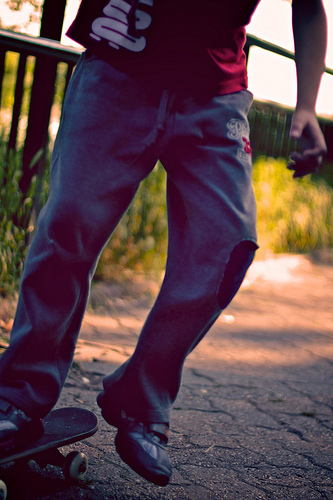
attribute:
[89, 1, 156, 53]
text — white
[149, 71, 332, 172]
fence — black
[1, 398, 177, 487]
tennis shoes — dark blue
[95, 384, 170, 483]
shoe — black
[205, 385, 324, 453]
pavement — cracked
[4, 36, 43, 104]
fence — shining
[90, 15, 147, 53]
letter — white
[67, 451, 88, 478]
wheel — white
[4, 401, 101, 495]
skateboard — dark 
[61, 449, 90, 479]
wheels — white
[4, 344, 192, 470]
tennis shoes — black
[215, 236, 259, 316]
pad — blue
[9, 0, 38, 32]
leaves — green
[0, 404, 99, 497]
skateboard — black